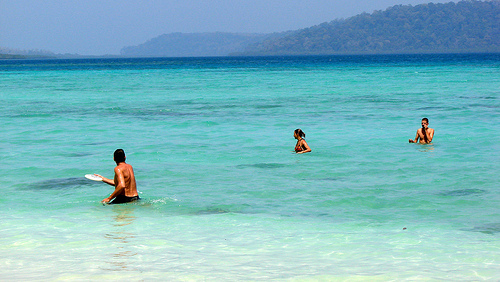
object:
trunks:
[108, 194, 139, 204]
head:
[113, 149, 126, 164]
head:
[421, 118, 429, 128]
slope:
[118, 0, 500, 59]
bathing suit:
[295, 138, 306, 152]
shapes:
[0, 150, 500, 237]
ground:
[412, 146, 455, 180]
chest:
[419, 130, 425, 138]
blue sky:
[0, 0, 500, 58]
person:
[293, 128, 312, 153]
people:
[94, 117, 434, 205]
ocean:
[0, 64, 500, 280]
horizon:
[0, 51, 500, 61]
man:
[409, 117, 435, 145]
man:
[85, 149, 139, 207]